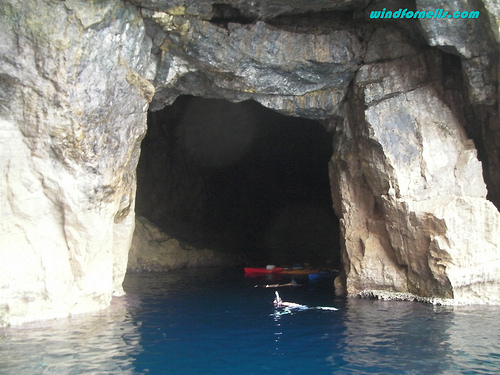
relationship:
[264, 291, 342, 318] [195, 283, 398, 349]
person swimming in water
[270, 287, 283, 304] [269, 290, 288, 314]
snorkel on man's face